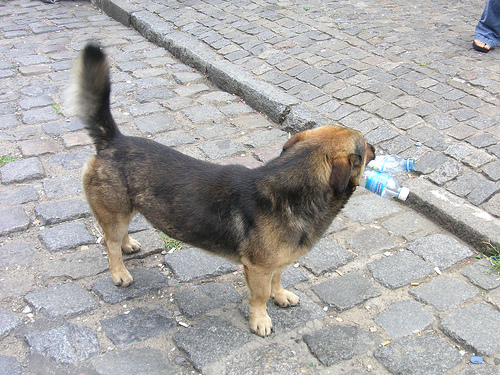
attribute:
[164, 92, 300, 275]
dog — brown, black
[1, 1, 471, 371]
road — paved, bricked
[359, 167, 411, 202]
bottle — clear , plastic 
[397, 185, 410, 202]
bottle cap — white 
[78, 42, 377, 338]
dog — black and brown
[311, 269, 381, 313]
brick — black 